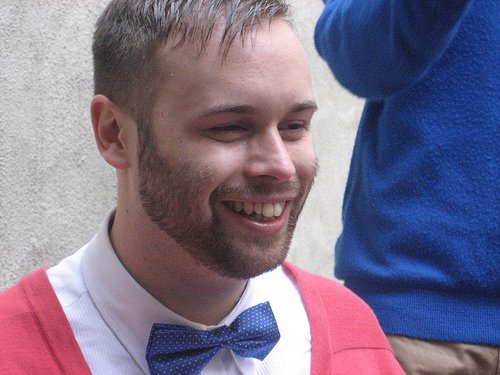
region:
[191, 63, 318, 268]
the face of a man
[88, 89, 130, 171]
the ear of a person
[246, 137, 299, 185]
the nose on a face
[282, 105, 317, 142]
the eye of a man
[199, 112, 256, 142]
the eye of a man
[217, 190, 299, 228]
the mouth of a man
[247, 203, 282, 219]
teeth in a mouth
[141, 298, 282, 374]
a blue bow tie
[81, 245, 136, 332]
the collar of a white shirt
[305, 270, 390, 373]
the fabric of a red sweater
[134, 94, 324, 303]
the man has beard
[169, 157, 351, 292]
the man has beard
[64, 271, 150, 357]
the shirt is white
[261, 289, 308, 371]
the shirt is white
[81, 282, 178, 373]
the shirt is white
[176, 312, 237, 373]
the shirt is white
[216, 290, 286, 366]
the shirt is white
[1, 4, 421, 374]
man who is smiling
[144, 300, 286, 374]
blue and white bowtie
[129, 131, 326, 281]
beard on the face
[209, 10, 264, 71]
tuft of hair laying on the forehead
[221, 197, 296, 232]
smile that exposes teeth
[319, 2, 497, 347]
bright blue sweater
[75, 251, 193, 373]
white collar is down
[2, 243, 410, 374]
red sweater over the white shirt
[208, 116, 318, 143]
eyes are squinted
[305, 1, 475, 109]
elbow is bent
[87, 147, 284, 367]
man is wearing a ribbon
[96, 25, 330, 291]
the man is smiling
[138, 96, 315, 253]
the man is smiling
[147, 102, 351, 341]
the man is smiling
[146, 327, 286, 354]
a blue bow tie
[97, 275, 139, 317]
white collard shirt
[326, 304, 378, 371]
a pink vest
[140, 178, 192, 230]
the man has a beard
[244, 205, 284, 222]
teeth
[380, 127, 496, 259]
a blue sweater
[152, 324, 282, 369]
polka dots on the blue tie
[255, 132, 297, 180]
nose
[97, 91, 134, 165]
the mans ear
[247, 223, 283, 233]
the mans lips